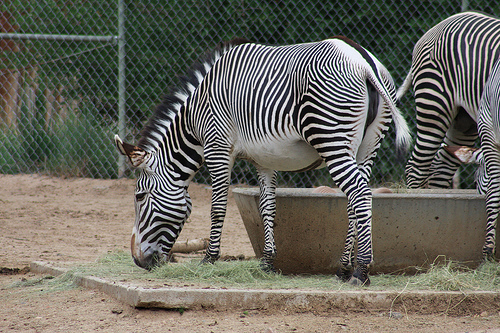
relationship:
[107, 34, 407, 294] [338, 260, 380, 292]
zebra has hooves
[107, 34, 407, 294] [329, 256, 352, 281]
zebra has hooves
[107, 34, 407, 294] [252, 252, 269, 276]
zebra has hooves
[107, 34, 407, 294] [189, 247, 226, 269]
zebra has hooves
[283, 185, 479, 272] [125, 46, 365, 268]
gray tub next to zebras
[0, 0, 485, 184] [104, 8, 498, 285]
fence behind zebras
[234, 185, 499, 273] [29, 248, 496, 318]
gray tub on platform